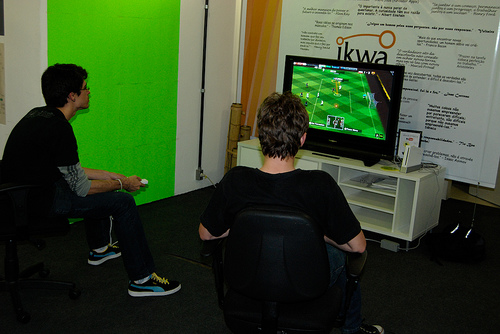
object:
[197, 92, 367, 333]
man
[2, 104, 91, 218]
shirt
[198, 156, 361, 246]
shirt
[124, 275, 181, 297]
shoes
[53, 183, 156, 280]
jeans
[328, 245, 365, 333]
jeans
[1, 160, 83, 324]
chair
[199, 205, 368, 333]
chair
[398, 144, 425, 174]
game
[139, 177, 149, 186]
controller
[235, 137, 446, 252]
tv stand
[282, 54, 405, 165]
television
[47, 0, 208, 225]
wall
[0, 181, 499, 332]
floor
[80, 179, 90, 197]
elbow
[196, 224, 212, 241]
elbow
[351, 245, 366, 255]
elbow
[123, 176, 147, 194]
hand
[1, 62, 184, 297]
men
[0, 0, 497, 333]
room